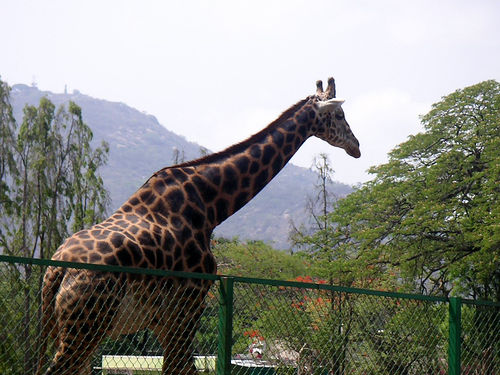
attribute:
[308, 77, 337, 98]
horns — animal, giraffe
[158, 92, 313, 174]
hair — animal, giraffe, neck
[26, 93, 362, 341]
giraffe — black, brown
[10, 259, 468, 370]
fence — green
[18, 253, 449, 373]
fence — green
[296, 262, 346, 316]
flowers — red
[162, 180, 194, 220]
spot — black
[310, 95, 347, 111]
ear — one, giraffe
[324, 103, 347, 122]
eye — giraffe, round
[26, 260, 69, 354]
tail — giraffe, one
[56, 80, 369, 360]
giraffe — one, adult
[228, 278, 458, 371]
fence — chain, link, green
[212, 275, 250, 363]
post — green, metal, fence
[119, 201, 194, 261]
spots — brown, dark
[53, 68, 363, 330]
giraffe — one, spotted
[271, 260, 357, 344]
leaves — red, autumn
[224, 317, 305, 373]
building — short, white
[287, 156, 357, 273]
tree — thin, leafless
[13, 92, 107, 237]
tree — tall, willow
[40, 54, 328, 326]
giraffe — living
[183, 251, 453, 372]
fence — green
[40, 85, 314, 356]
zebra — brown, yellow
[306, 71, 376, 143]
ear — brown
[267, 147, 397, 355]
tree — thin, dying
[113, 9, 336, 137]
sky — bright white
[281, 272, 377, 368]
leaves — orange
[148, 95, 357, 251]
neck — long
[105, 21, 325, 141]
sky — clear, blue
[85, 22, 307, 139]
sky — blue, clear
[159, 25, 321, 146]
sky — clear, blue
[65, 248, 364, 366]
gate — green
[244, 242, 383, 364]
leaves — orange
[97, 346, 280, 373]
building — white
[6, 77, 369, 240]
hills — high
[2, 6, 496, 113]
sky — blue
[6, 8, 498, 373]
outside — sunny